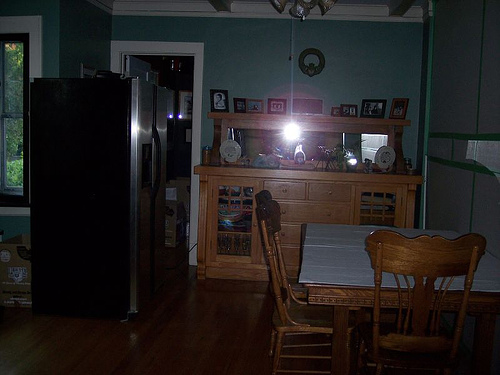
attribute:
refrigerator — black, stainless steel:
[35, 79, 178, 317]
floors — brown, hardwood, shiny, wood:
[133, 276, 273, 362]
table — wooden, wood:
[304, 206, 490, 320]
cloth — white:
[300, 220, 381, 279]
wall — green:
[213, 19, 422, 102]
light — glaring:
[277, 119, 296, 137]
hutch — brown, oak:
[202, 104, 421, 309]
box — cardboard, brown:
[5, 237, 32, 307]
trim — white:
[0, 15, 49, 36]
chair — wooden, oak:
[372, 235, 468, 364]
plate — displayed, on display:
[217, 146, 242, 164]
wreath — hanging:
[288, 47, 333, 90]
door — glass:
[218, 172, 262, 275]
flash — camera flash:
[279, 122, 302, 151]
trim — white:
[114, 33, 207, 68]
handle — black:
[144, 147, 165, 177]